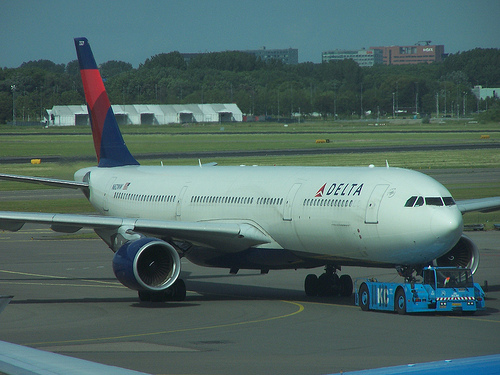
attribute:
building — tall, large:
[372, 45, 442, 62]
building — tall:
[320, 49, 384, 67]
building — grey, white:
[44, 102, 245, 128]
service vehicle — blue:
[354, 265, 485, 315]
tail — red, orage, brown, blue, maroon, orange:
[73, 35, 139, 167]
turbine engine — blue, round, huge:
[113, 237, 181, 290]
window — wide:
[426, 197, 443, 207]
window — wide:
[441, 196, 456, 206]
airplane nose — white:
[436, 211, 462, 238]